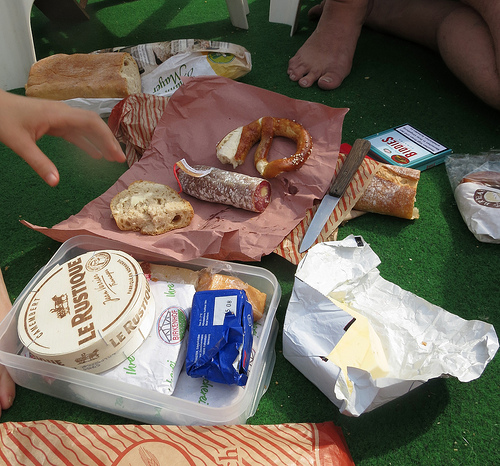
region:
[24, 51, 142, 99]
A loaf of bread.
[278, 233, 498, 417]
A crumpled paper wrapper.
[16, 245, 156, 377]
A white and brown container.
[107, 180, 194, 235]
A slice of bread.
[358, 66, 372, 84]
A crumb on the ground.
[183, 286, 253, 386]
A blue package in a container.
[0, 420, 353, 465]
Striped packaging on the ground.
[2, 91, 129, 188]
A person's hand reaching.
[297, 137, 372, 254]
A knife laying on paper.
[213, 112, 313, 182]
A pretzel on paper.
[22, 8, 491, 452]
scene is a snack eating area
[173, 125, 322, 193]
breads are brown in color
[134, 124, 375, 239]
bread on a brown paper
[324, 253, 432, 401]
the paper is white in color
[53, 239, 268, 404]
snacks in a colorless tin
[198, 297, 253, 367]
the wrapped snack is blue in color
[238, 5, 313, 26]
the seats are white in color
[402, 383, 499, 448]
the carpet is green in colour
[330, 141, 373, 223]
the knife handle is wooden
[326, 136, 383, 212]
knife handle is brown in color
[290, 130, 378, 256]
knife next to food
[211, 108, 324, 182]
pretzel on a paper wrapper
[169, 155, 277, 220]
sausage next to a pretzel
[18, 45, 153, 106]
bread on a paper bag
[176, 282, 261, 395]
blue wrapper in a plastic container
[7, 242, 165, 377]
round container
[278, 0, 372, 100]
persons foot on a green surface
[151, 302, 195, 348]
logo on a wrapper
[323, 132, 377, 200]
wooden handle on a knife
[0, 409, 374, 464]
red and brown bag on the ground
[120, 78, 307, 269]
pretzel on brown paper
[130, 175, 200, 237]
brown bread on paper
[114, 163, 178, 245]
butter on brown bread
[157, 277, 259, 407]
blue packet in container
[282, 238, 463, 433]
butter in white paper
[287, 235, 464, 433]
paper on green table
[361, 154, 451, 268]
bread has end sliced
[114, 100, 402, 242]
bread under striped paper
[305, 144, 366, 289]
knife on striped paper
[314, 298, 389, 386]
butter is bright yellow